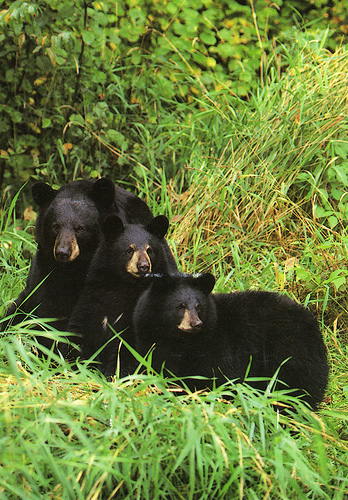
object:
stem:
[61, 1, 87, 121]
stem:
[15, 35, 31, 83]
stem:
[119, 84, 131, 133]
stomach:
[63, 278, 148, 369]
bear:
[70, 212, 178, 377]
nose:
[52, 238, 79, 266]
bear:
[0, 173, 154, 357]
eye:
[48, 219, 65, 234]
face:
[114, 229, 162, 283]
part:
[27, 165, 117, 212]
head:
[100, 214, 170, 286]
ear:
[100, 212, 126, 241]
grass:
[0, 267, 347, 499]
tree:
[64, 1, 88, 148]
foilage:
[182, 155, 347, 277]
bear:
[131, 271, 329, 411]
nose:
[131, 253, 153, 278]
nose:
[179, 312, 204, 335]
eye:
[173, 298, 188, 310]